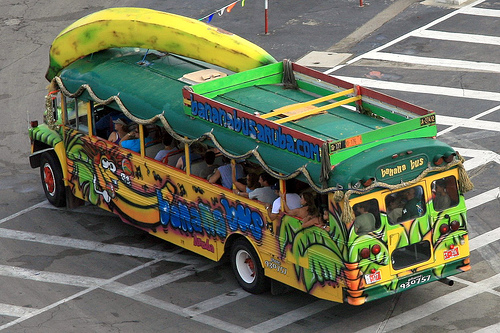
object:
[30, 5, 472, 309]
bus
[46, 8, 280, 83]
banana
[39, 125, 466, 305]
paint